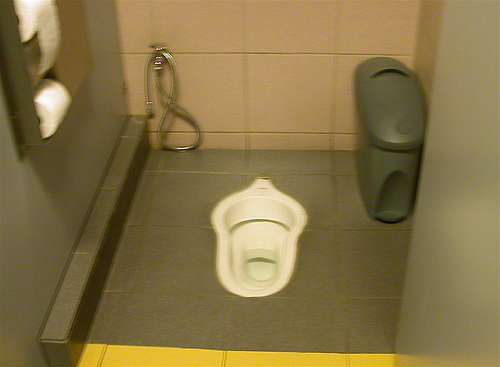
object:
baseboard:
[36, 112, 153, 365]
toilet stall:
[4, 1, 484, 365]